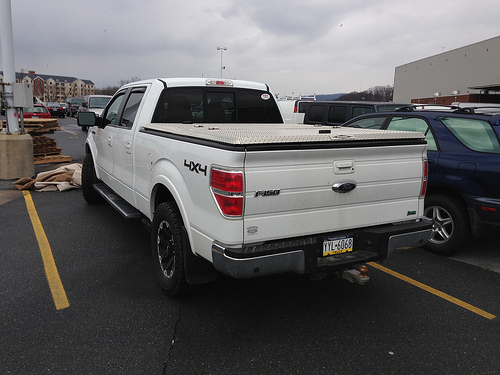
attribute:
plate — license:
[321, 235, 352, 257]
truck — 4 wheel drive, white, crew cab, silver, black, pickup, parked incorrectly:
[76, 75, 435, 298]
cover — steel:
[141, 120, 426, 148]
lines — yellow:
[20, 186, 68, 312]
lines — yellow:
[59, 125, 77, 137]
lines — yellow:
[364, 257, 497, 321]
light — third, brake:
[205, 78, 234, 90]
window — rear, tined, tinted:
[149, 84, 287, 126]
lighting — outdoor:
[215, 45, 227, 52]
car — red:
[13, 102, 52, 124]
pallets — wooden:
[2, 116, 63, 138]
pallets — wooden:
[28, 134, 74, 166]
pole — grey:
[1, 1, 23, 135]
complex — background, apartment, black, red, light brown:
[1, 69, 96, 108]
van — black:
[295, 98, 421, 135]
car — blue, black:
[322, 110, 500, 257]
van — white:
[271, 99, 316, 126]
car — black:
[44, 99, 67, 119]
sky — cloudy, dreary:
[2, 1, 500, 95]